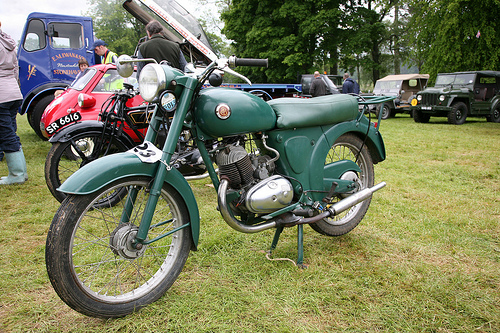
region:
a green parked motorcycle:
[41, 54, 391, 316]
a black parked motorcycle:
[42, 86, 240, 213]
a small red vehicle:
[41, 61, 163, 153]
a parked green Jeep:
[409, 68, 495, 123]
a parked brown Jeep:
[363, 69, 426, 117]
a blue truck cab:
[14, 11, 98, 134]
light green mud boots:
[0, 148, 28, 184]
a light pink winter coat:
[0, 29, 25, 102]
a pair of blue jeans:
[1, 102, 20, 152]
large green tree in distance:
[221, 2, 314, 85]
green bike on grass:
[107, 95, 339, 286]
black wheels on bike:
[55, 165, 140, 302]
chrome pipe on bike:
[215, 146, 407, 238]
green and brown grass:
[349, 231, 447, 320]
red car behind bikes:
[15, 10, 140, 142]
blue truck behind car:
[20, 3, 102, 145]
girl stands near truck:
[0, 18, 61, 173]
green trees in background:
[206, 3, 496, 73]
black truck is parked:
[367, 62, 499, 145]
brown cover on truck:
[372, 71, 419, 117]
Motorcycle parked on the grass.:
[44, 54, 401, 318]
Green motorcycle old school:
[44, 36, 411, 319]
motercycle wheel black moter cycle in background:
[30, 128, 213, 320]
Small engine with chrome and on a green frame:
[204, 122, 312, 238]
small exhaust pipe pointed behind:
[323, 178, 394, 225]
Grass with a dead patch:
[396, 204, 490, 316]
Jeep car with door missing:
[404, 48, 499, 135]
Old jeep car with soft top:
[360, 73, 425, 124]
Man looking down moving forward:
[82, 26, 119, 68]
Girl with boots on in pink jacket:
[0, 12, 50, 187]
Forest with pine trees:
[281, 10, 480, 61]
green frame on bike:
[119, 81, 407, 284]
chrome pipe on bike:
[206, 149, 389, 246]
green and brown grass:
[345, 206, 478, 306]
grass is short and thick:
[342, 196, 476, 301]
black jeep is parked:
[401, 57, 496, 122]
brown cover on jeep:
[370, 67, 427, 134]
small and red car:
[55, 60, 170, 145]